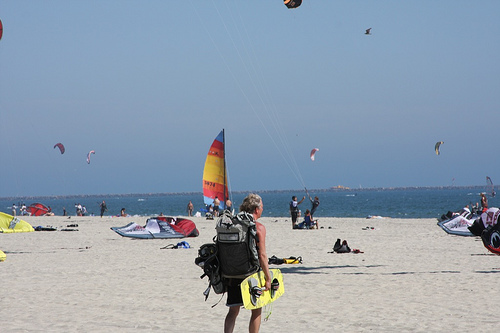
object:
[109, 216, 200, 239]
vehicle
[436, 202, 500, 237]
vehicle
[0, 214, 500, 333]
sandy ground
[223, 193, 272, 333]
man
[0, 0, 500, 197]
sky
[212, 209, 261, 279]
backpack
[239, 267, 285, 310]
board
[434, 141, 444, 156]
kite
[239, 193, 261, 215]
hair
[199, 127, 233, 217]
sailboat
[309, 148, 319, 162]
parasail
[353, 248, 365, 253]
items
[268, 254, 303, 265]
bag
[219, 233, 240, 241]
patch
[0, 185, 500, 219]
blue sea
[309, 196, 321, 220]
boy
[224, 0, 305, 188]
lines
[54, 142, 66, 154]
parasail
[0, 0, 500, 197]
air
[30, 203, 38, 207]
patch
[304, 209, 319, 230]
person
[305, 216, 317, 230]
chair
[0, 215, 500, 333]
sand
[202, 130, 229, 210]
sail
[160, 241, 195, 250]
object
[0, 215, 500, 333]
beach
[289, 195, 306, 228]
person